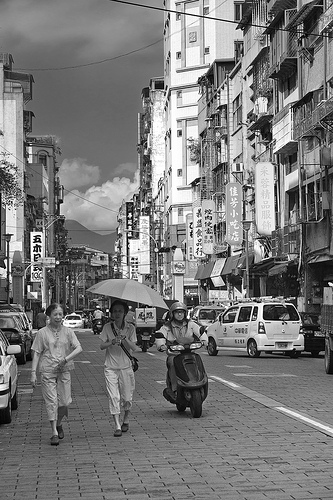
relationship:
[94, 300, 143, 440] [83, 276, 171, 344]
woman carrying an umbrella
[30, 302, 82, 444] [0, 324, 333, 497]
woman walking down road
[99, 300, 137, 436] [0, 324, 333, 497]
woman walking down road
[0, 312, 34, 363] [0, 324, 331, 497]
vehicle on road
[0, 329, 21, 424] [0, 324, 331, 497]
vehicle on road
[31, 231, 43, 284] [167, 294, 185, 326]
helmet on head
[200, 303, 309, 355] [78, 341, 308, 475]
car on road